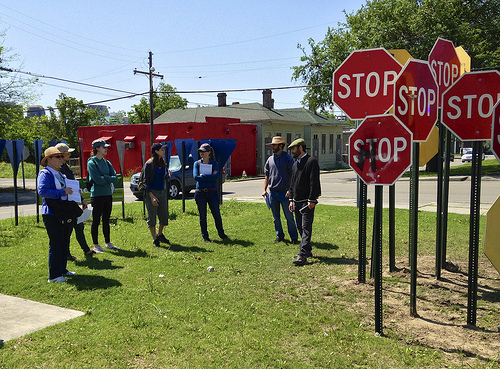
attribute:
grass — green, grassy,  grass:
[1, 193, 499, 367]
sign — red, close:
[334, 46, 402, 117]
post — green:
[370, 185, 389, 334]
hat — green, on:
[288, 137, 303, 151]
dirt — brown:
[339, 244, 498, 368]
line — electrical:
[73, 86, 329, 106]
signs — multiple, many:
[328, 38, 499, 189]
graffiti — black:
[356, 138, 380, 173]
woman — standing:
[192, 144, 228, 242]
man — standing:
[287, 135, 325, 266]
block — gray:
[1, 288, 85, 343]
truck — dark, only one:
[131, 154, 206, 198]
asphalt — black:
[4, 156, 496, 221]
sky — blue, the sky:
[0, 0, 393, 117]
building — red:
[75, 113, 263, 184]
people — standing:
[41, 136, 318, 287]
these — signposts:
[335, 36, 496, 308]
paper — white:
[197, 160, 214, 180]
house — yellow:
[255, 106, 344, 172]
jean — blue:
[266, 190, 298, 235]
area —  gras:
[156, 310, 245, 358]